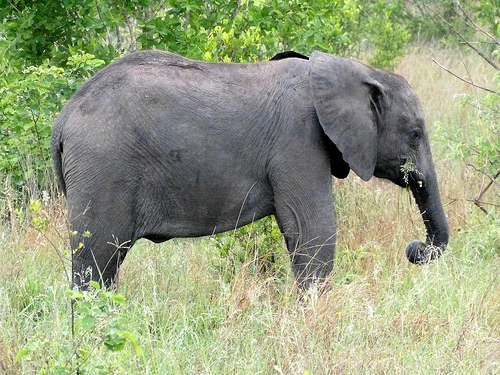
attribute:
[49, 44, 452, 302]
elephant — standing, outdoors, eating, grey, alone, grazing, large, gray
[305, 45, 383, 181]
right ear — grey, large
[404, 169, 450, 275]
trunk — grey, curled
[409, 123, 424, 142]
right eye — black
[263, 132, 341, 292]
front leg — grey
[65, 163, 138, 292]
hind leg — grey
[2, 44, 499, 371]
grass — yellow, long, tall, mixed, dry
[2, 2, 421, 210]
trees — green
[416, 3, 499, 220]
branches — bare, dead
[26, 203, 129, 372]
tree — small